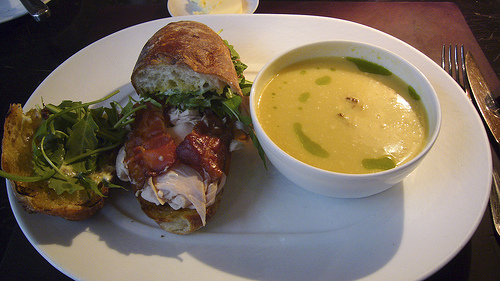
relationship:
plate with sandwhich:
[436, 172, 483, 241] [81, 37, 223, 237]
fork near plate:
[442, 37, 471, 76] [436, 172, 483, 241]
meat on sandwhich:
[160, 165, 209, 213] [81, 37, 223, 237]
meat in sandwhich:
[160, 165, 209, 213] [81, 37, 223, 237]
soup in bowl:
[322, 77, 381, 128] [406, 65, 449, 111]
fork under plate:
[442, 37, 471, 76] [436, 172, 483, 241]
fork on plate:
[442, 37, 471, 76] [436, 172, 483, 241]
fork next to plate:
[442, 37, 471, 76] [436, 172, 483, 241]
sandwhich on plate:
[81, 37, 223, 237] [436, 172, 483, 241]